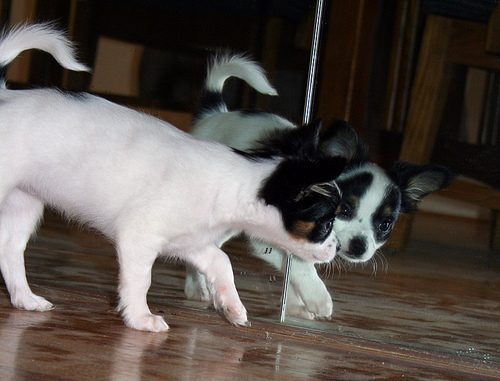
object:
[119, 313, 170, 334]
puppy paw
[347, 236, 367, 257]
nose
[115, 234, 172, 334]
leg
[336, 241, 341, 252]
nose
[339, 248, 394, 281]
whiskers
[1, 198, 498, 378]
floor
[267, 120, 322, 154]
ear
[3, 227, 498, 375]
hardwood floors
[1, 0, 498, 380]
room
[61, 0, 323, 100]
closet mirror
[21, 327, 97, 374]
dust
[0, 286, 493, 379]
floor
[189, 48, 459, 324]
reflection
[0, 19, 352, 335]
dog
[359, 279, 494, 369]
floor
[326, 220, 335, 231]
eye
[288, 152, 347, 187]
ear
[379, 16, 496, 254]
chair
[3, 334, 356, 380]
wood floor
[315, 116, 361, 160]
ear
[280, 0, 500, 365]
mirror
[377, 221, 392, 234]
eye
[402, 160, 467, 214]
ear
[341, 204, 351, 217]
eye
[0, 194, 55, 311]
leg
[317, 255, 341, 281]
whiskers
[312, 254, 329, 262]
mouth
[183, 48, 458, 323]
dog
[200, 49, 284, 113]
tail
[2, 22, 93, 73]
end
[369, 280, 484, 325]
reflection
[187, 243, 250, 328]
leg